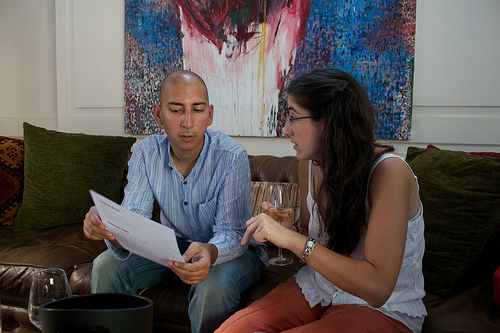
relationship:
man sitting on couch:
[82, 69, 269, 332] [1, 136, 500, 331]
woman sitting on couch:
[214, 69, 427, 332] [1, 136, 500, 331]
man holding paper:
[82, 69, 269, 332] [88, 188, 185, 269]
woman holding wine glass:
[214, 69, 427, 332] [266, 182, 291, 264]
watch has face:
[299, 237, 317, 266] [307, 240, 315, 249]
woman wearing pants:
[214, 69, 427, 332] [213, 272, 412, 332]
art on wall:
[125, 0, 417, 141] [1, 0, 500, 157]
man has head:
[82, 69, 269, 332] [152, 70, 214, 151]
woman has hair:
[214, 69, 427, 332] [288, 67, 393, 256]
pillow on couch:
[1, 136, 25, 231] [1, 136, 500, 331]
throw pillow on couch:
[13, 121, 136, 232] [1, 136, 500, 331]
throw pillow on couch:
[405, 146, 500, 292] [1, 136, 500, 331]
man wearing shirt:
[82, 69, 269, 332] [103, 130, 253, 267]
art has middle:
[125, 0, 417, 141] [178, 1, 310, 140]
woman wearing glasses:
[214, 69, 427, 332] [287, 110, 313, 124]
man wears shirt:
[82, 69, 269, 332] [103, 130, 253, 267]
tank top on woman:
[294, 153, 426, 333] [214, 69, 427, 332]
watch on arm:
[299, 237, 317, 266] [241, 175, 412, 308]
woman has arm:
[214, 69, 427, 332] [241, 175, 412, 308]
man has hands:
[82, 69, 269, 332] [82, 204, 212, 286]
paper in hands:
[88, 188, 185, 269] [82, 204, 212, 286]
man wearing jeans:
[82, 69, 269, 332] [91, 234, 262, 333]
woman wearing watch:
[214, 69, 427, 332] [299, 237, 317, 266]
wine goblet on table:
[28, 268, 73, 333] [1, 329, 174, 332]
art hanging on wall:
[125, 0, 417, 141] [1, 0, 500, 157]